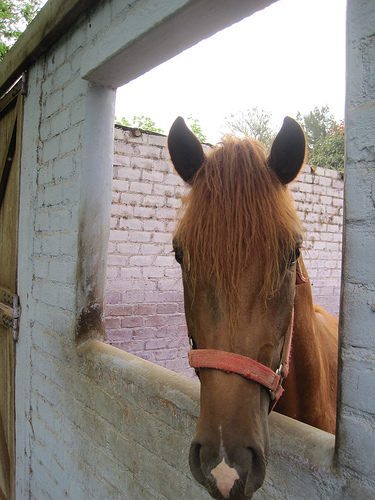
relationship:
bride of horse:
[176, 234, 308, 395] [152, 104, 356, 498]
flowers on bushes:
[323, 122, 344, 143] [248, 98, 341, 164]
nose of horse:
[194, 429, 264, 499] [152, 104, 356, 498]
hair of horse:
[182, 128, 297, 306] [152, 104, 356, 498]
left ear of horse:
[262, 112, 305, 186] [152, 104, 356, 498]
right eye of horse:
[173, 238, 189, 270] [152, 104, 356, 498]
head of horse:
[151, 115, 314, 493] [152, 104, 356, 498]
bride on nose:
[176, 234, 308, 395] [194, 429, 264, 499]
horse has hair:
[152, 104, 356, 498] [182, 128, 297, 306]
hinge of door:
[10, 294, 23, 339] [1, 69, 45, 500]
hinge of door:
[18, 70, 30, 97] [1, 69, 45, 500]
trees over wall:
[1, 2, 231, 147] [23, 6, 372, 500]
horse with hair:
[152, 104, 356, 498] [182, 128, 297, 306]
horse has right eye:
[152, 104, 356, 498] [173, 238, 189, 270]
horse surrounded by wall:
[152, 104, 356, 498] [23, 6, 372, 500]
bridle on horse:
[178, 295, 306, 404] [152, 104, 356, 498]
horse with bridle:
[152, 104, 356, 498] [178, 295, 306, 404]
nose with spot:
[194, 429, 264, 499] [208, 441, 242, 500]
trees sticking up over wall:
[1, 2, 231, 147] [23, 6, 372, 500]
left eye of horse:
[284, 242, 305, 265] [152, 104, 356, 498]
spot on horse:
[208, 441, 242, 500] [152, 104, 356, 498]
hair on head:
[182, 128, 297, 306] [151, 115, 314, 493]